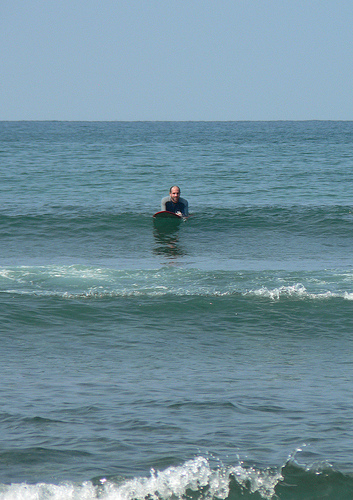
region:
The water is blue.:
[4, 117, 349, 494]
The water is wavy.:
[0, 131, 347, 494]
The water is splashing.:
[0, 113, 349, 494]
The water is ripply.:
[0, 118, 345, 496]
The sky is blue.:
[0, 2, 350, 122]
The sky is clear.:
[1, 2, 350, 117]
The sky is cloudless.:
[4, 3, 351, 116]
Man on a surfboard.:
[137, 174, 207, 244]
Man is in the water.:
[134, 174, 222, 243]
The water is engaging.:
[3, 122, 351, 498]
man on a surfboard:
[128, 152, 203, 264]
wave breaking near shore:
[114, 450, 269, 498]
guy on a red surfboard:
[128, 187, 258, 265]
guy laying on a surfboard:
[140, 155, 206, 249]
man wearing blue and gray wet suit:
[140, 181, 193, 214]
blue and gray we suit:
[156, 198, 169, 209]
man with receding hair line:
[150, 171, 190, 202]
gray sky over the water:
[148, 57, 288, 155]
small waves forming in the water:
[27, 210, 223, 336]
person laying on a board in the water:
[108, 179, 230, 265]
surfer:
[152, 173, 191, 226]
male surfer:
[154, 182, 189, 227]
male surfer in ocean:
[151, 184, 191, 227]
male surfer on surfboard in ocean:
[149, 173, 196, 219]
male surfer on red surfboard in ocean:
[155, 184, 191, 225]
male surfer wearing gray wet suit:
[151, 181, 191, 211]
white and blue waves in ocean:
[18, 458, 130, 497]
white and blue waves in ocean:
[141, 405, 260, 483]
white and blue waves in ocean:
[231, 262, 313, 323]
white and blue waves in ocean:
[12, 252, 113, 314]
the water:
[123, 382, 216, 489]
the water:
[173, 384, 221, 428]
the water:
[174, 389, 204, 440]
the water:
[162, 391, 211, 455]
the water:
[140, 392, 180, 466]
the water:
[167, 412, 234, 497]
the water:
[144, 399, 203, 475]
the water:
[170, 452, 211, 496]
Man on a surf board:
[156, 186, 204, 238]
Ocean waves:
[61, 249, 301, 320]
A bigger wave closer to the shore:
[6, 448, 287, 493]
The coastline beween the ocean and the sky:
[0, 110, 348, 124]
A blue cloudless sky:
[0, 14, 288, 97]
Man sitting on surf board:
[152, 169, 188, 229]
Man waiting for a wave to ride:
[163, 178, 204, 225]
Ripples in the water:
[153, 134, 298, 186]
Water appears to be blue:
[80, 148, 269, 157]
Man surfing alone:
[161, 177, 253, 224]